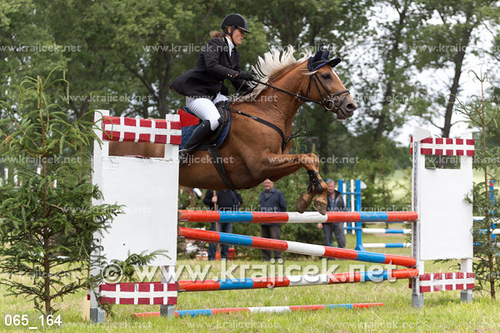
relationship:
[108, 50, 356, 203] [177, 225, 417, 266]
horse jumps over bar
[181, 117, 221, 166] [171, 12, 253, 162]
boots on jockey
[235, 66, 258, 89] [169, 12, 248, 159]
gloves on rider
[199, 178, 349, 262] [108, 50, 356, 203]
people watching horse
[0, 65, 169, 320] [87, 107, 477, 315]
tree beside barrier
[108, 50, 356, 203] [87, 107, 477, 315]
horse jumping beside barrier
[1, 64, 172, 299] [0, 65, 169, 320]
leaves growing on tree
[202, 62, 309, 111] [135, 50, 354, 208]
mane on horse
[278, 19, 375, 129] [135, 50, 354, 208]
head on horse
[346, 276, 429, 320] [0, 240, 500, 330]
green grass growing on ground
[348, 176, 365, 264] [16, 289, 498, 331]
post sticking out of ground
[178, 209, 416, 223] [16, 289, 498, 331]
bar sticking out of ground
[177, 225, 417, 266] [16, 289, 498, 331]
bar sticking out of ground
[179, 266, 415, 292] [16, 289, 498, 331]
bar sticking out of ground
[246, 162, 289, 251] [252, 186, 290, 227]
man in jacket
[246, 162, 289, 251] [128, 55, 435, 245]
man watching horse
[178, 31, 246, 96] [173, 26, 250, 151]
jacket on woman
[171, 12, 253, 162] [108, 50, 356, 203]
jockey riding horse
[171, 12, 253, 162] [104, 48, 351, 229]
jockey riding horse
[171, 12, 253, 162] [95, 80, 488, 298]
jockey jumping over hurdles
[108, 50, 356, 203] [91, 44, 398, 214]
horse jumping over hurdles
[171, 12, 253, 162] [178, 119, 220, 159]
jockey wearing boots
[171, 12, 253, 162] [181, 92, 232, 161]
jockey wearing pants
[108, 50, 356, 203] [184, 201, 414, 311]
horse jumping over obstacle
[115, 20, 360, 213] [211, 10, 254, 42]
horse wearing hat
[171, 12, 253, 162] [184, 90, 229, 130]
jockey wearing pants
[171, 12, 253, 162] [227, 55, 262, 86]
jockey wearing gloves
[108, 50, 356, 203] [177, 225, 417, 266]
horse jumping over a bar